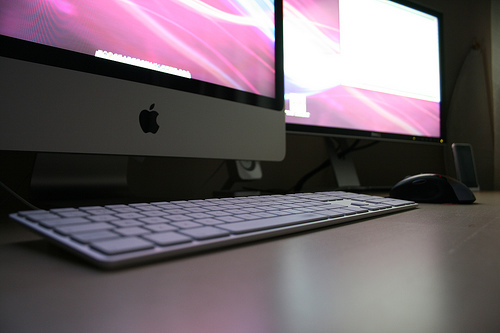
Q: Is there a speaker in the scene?
A: Yes, there is a speaker.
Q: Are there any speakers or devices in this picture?
A: Yes, there is a speaker.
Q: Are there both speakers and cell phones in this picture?
A: No, there is a speaker but no cell phones.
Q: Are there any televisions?
A: No, there are no televisions.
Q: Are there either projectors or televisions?
A: No, there are no televisions or projectors.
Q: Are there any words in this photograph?
A: Yes, there are words.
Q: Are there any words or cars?
A: Yes, there are words.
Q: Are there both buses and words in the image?
A: No, there are words but no buses.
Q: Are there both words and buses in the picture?
A: No, there are words but no buses.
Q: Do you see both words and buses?
A: No, there are words but no buses.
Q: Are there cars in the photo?
A: No, there are no cars.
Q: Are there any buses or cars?
A: No, there are no cars or buses.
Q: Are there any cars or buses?
A: No, there are no cars or buses.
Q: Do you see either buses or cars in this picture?
A: No, there are no cars or buses.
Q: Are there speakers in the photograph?
A: Yes, there are speakers.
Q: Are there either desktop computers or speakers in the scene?
A: Yes, there are speakers.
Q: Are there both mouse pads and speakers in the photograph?
A: No, there are speakers but no mouse pads.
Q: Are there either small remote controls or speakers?
A: Yes, there are small speakers.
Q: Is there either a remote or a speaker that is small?
A: Yes, the speakers are small.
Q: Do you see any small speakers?
A: Yes, there are small speakers.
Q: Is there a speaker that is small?
A: Yes, there are speakers that are small.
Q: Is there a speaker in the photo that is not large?
A: Yes, there are small speakers.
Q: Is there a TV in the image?
A: No, there are no televisions.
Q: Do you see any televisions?
A: No, there are no televisions.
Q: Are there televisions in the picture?
A: No, there are no televisions.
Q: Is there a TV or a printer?
A: No, there are no televisions or printers.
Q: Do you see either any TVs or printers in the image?
A: No, there are no TVs or printers.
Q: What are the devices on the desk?
A: The devices are speakers.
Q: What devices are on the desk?
A: The devices are speakers.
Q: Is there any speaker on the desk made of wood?
A: Yes, there are speakers on the desk.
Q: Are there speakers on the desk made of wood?
A: Yes, there are speakers on the desk.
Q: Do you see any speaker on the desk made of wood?
A: Yes, there are speakers on the desk.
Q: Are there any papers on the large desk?
A: No, there are speakers on the desk.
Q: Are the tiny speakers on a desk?
A: Yes, the speakers are on a desk.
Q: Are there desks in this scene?
A: Yes, there is a desk.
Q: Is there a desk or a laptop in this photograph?
A: Yes, there is a desk.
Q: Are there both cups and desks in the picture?
A: No, there is a desk but no cups.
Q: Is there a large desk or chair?
A: Yes, there is a large desk.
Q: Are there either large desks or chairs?
A: Yes, there is a large desk.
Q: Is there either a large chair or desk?
A: Yes, there is a large desk.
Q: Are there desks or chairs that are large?
A: Yes, the desk is large.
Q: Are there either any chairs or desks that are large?
A: Yes, the desk is large.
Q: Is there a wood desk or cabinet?
A: Yes, there is a wood desk.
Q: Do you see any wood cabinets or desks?
A: Yes, there is a wood desk.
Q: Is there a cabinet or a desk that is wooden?
A: Yes, the desk is wooden.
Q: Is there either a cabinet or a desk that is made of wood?
A: Yes, the desk is made of wood.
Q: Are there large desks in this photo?
A: Yes, there is a large desk.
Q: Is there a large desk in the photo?
A: Yes, there is a large desk.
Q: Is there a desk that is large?
A: Yes, there is a desk that is large.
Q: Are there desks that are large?
A: Yes, there is a desk that is large.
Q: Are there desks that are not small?
A: Yes, there is a large desk.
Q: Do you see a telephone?
A: No, there are no phones.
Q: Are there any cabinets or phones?
A: No, there are no phones or cabinets.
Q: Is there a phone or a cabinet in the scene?
A: No, there are no phones or cabinets.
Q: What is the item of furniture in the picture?
A: The piece of furniture is a desk.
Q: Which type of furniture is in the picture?
A: The furniture is a desk.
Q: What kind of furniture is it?
A: The piece of furniture is a desk.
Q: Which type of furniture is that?
A: This is a desk.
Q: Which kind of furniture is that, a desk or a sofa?
A: This is a desk.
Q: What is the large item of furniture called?
A: The piece of furniture is a desk.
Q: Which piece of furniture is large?
A: The piece of furniture is a desk.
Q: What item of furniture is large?
A: The piece of furniture is a desk.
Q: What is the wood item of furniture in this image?
A: The piece of furniture is a desk.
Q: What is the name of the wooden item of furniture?
A: The piece of furniture is a desk.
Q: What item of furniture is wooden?
A: The piece of furniture is a desk.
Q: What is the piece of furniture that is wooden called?
A: The piece of furniture is a desk.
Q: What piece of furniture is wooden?
A: The piece of furniture is a desk.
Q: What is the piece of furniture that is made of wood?
A: The piece of furniture is a desk.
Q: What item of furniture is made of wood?
A: The piece of furniture is a desk.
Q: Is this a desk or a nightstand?
A: This is a desk.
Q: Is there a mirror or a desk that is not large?
A: No, there is a desk but it is large.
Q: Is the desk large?
A: Yes, the desk is large.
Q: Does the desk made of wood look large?
A: Yes, the desk is large.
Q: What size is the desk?
A: The desk is large.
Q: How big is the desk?
A: The desk is large.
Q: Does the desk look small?
A: No, the desk is large.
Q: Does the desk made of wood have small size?
A: No, the desk is large.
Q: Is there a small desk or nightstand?
A: No, there is a desk but it is large.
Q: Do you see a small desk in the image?
A: No, there is a desk but it is large.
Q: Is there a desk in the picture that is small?
A: No, there is a desk but it is large.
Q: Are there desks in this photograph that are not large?
A: No, there is a desk but it is large.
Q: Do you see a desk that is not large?
A: No, there is a desk but it is large.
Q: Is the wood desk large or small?
A: The desk is large.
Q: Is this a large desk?
A: Yes, this is a large desk.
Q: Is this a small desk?
A: No, this is a large desk.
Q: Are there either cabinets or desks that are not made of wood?
A: No, there is a desk but it is made of wood.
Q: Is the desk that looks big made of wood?
A: Yes, the desk is made of wood.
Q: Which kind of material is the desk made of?
A: The desk is made of wood.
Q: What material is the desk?
A: The desk is made of wood.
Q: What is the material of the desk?
A: The desk is made of wood.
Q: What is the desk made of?
A: The desk is made of wood.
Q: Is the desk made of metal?
A: No, the desk is made of wood.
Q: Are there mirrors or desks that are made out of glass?
A: No, there is a desk but it is made of wood.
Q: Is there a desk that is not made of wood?
A: No, there is a desk but it is made of wood.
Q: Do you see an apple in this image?
A: Yes, there is an apple.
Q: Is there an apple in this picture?
A: Yes, there is an apple.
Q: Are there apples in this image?
A: Yes, there is an apple.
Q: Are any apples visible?
A: Yes, there is an apple.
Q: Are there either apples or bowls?
A: Yes, there is an apple.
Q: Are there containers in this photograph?
A: No, there are no containers.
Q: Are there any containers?
A: No, there are no containers.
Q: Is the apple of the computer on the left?
A: Yes, the apple is on the left of the image.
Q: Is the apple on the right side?
A: No, the apple is on the left of the image.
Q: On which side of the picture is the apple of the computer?
A: The apple is on the left of the image.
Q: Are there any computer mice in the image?
A: Yes, there is a computer mouse.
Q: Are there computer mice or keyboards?
A: Yes, there is a computer mouse.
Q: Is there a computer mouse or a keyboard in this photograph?
A: Yes, there is a computer mouse.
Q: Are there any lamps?
A: No, there are no lamps.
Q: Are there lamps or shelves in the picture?
A: No, there are no lamps or shelves.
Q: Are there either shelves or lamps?
A: No, there are no lamps or shelves.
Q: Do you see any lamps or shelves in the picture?
A: No, there are no lamps or shelves.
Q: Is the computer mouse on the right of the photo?
A: Yes, the computer mouse is on the right of the image.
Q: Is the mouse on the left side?
A: No, the mouse is on the right of the image.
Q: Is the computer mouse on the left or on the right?
A: The computer mouse is on the right of the image.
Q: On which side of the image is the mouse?
A: The mouse is on the right of the image.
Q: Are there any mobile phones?
A: No, there are no mobile phones.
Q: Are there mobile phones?
A: No, there are no mobile phones.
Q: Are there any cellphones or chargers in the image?
A: No, there are no cellphones or chargers.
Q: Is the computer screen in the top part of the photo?
A: Yes, the screen is in the top of the image.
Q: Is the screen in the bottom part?
A: No, the screen is in the top of the image.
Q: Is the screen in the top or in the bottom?
A: The screen is in the top of the image.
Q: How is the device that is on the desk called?
A: The device is a screen.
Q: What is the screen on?
A: The screen is on the desk.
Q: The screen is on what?
A: The screen is on the desk.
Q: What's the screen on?
A: The screen is on the desk.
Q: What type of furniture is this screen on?
A: The screen is on the desk.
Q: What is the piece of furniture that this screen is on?
A: The piece of furniture is a desk.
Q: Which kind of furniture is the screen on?
A: The screen is on the desk.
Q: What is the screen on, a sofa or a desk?
A: The screen is on a desk.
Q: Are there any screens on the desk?
A: Yes, there is a screen on the desk.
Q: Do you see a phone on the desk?
A: No, there is a screen on the desk.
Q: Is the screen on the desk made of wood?
A: Yes, the screen is on the desk.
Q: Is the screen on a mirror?
A: No, the screen is on the desk.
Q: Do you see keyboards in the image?
A: Yes, there is a keyboard.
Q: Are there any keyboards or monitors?
A: Yes, there is a keyboard.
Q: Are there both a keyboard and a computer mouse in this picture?
A: Yes, there are both a keyboard and a computer mouse.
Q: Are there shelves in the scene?
A: No, there are no shelves.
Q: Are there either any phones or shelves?
A: No, there are no shelves or phones.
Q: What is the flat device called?
A: The device is a keyboard.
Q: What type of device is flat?
A: The device is a keyboard.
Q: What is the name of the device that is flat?
A: The device is a keyboard.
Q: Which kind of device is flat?
A: The device is a keyboard.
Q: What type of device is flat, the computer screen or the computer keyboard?
A: The keyboard is flat.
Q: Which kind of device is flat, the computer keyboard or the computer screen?
A: The keyboard is flat.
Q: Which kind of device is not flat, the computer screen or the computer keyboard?
A: The screen is not flat.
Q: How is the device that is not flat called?
A: The device is a screen.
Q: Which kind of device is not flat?
A: The device is a screen.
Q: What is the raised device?
A: The device is a keyboard.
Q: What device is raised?
A: The device is a keyboard.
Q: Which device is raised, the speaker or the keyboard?
A: The keyboard is raised.